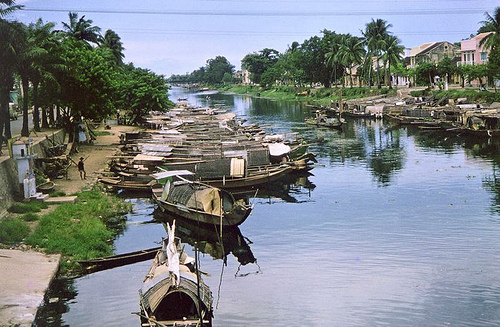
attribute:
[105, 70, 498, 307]
river — town's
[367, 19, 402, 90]
trees — tall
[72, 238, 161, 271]
canoe — small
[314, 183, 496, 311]
water — calm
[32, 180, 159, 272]
grass — green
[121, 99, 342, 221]
boats — wooden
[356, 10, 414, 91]
tree —  palm,  Group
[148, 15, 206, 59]
sky — clear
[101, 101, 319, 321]
boats — parked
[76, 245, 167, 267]
canoe — thin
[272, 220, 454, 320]
water — calm, blue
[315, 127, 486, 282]
water — river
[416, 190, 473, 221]
water — calm